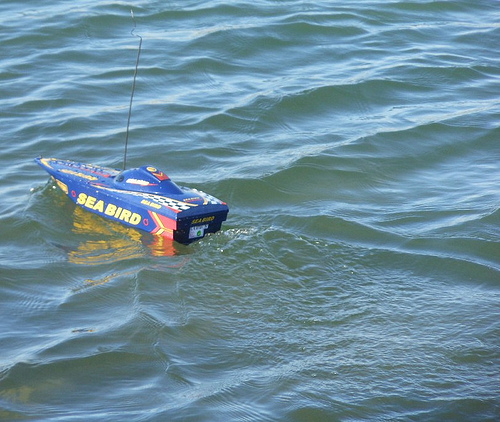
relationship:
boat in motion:
[36, 155, 228, 246] [175, 228, 467, 405]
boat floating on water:
[36, 155, 228, 246] [0, 0, 499, 421]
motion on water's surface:
[189, 227, 500, 421] [13, 10, 483, 400]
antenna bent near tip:
[123, 7, 141, 165] [130, 9, 142, 39]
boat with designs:
[36, 155, 228, 246] [140, 187, 228, 245]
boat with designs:
[36, 155, 228, 246] [41, 145, 114, 178]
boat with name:
[36, 155, 228, 246] [77, 192, 141, 224]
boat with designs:
[36, 155, 228, 246] [126, 161, 170, 183]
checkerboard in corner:
[143, 186, 190, 209] [145, 189, 195, 240]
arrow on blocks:
[154, 211, 162, 240] [148, 210, 178, 239]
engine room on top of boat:
[114, 166, 183, 195] [31, 140, 237, 240]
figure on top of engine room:
[147, 153, 173, 181] [114, 166, 183, 195]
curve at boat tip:
[38, 150, 62, 167] [35, 138, 76, 199]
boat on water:
[36, 155, 228, 246] [0, 0, 499, 421]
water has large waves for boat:
[0, 0, 499, 421] [36, 155, 228, 246]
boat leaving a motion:
[36, 155, 228, 246] [189, 227, 500, 421]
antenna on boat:
[116, 10, 144, 171] [20, 148, 233, 256]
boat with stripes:
[31, 140, 237, 240] [149, 200, 183, 241]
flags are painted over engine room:
[195, 180, 228, 215] [152, 180, 233, 211]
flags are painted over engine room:
[155, 190, 196, 218] [152, 180, 233, 211]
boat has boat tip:
[36, 155, 228, 246] [35, 155, 73, 175]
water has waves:
[28, 242, 498, 416] [78, 259, 185, 373]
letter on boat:
[99, 202, 140, 232] [27, 128, 228, 268]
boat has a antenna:
[36, 155, 228, 246] [123, 7, 141, 165]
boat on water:
[36, 155, 228, 246] [16, 246, 277, 418]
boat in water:
[36, 155, 228, 246] [10, 197, 299, 415]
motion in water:
[189, 227, 500, 421] [154, 130, 475, 388]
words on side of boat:
[68, 186, 148, 231] [18, 130, 263, 286]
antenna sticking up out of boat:
[123, 7, 141, 165] [27, 135, 245, 276]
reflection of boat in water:
[36, 200, 146, 281] [14, 211, 248, 347]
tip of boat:
[130, 30, 162, 68] [32, 144, 252, 284]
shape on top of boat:
[112, 157, 181, 202] [32, 144, 252, 284]